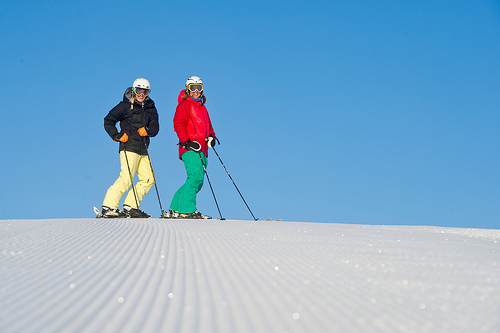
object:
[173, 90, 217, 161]
jacket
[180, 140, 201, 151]
ski gloves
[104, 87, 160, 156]
black jacket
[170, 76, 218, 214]
person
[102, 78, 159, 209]
person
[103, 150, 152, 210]
pants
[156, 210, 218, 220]
ski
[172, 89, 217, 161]
red jacket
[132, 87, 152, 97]
goggles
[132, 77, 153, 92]
helmets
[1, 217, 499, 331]
snow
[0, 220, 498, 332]
hill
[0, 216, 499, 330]
ground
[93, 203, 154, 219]
skis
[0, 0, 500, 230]
sky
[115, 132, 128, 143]
gloves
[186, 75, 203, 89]
helmets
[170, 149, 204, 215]
green pants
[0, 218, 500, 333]
slope